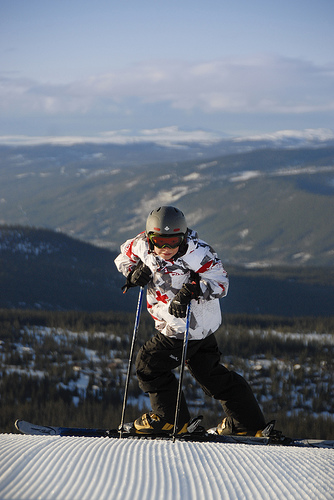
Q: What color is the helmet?
A: Gray.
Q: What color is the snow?
A: White.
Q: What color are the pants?
A: Black.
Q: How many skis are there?
A: Two.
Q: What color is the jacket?
A: White, red and gray.